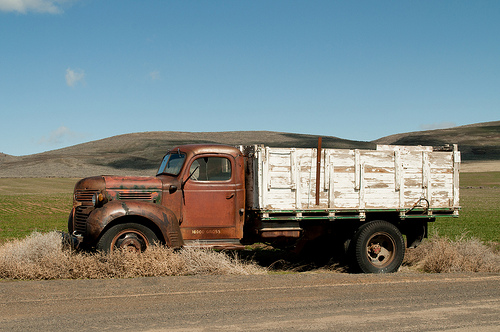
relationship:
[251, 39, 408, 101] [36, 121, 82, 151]
sky has cloud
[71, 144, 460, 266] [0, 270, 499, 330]
truck on road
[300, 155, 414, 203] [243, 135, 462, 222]
wood on back of truck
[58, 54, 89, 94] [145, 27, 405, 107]
cloud in sky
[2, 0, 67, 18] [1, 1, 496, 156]
cloud of sky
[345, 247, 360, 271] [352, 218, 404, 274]
edge of wheel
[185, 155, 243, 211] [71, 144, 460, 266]
part of truck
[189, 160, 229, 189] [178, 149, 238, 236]
part of door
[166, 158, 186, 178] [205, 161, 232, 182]
part of window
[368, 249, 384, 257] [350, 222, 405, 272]
part of wheel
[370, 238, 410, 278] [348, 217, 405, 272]
part of wheel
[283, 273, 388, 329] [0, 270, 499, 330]
part of road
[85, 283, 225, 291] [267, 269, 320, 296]
edge of road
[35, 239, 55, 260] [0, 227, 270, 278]
part of bush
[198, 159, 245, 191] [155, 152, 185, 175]
part of window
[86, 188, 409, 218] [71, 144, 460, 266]
side of truck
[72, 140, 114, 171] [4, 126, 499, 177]
edge of hill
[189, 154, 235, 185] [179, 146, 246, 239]
window on door